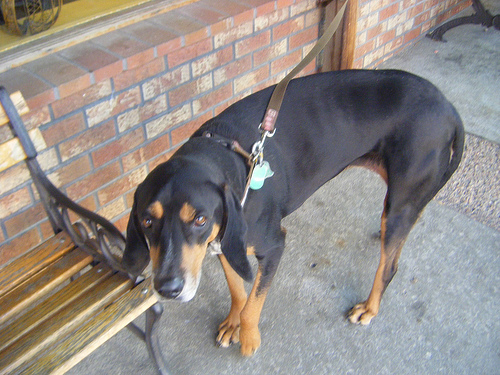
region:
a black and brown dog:
[111, 37, 476, 362]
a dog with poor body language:
[123, 60, 480, 362]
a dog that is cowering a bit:
[117, 57, 462, 364]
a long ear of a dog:
[210, 175, 264, 290]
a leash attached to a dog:
[250, 0, 353, 162]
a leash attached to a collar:
[249, 1, 351, 161]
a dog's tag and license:
[244, 134, 274, 202]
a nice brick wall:
[0, 4, 315, 221]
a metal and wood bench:
[0, 82, 176, 370]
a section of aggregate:
[433, 108, 495, 230]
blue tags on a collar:
[251, 160, 284, 191]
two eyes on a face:
[139, 214, 225, 230]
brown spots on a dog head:
[146, 193, 193, 223]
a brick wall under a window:
[116, 53, 229, 107]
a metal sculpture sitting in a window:
[1, 2, 69, 35]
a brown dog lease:
[291, 21, 339, 74]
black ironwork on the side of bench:
[40, 169, 128, 266]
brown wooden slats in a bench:
[26, 309, 99, 346]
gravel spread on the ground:
[457, 154, 497, 216]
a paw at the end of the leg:
[342, 301, 372, 328]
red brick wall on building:
[105, 33, 247, 110]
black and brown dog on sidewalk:
[125, 50, 471, 363]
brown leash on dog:
[236, 11, 349, 167]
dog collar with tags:
[219, 138, 276, 197]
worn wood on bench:
[4, 218, 94, 365]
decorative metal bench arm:
[28, 165, 142, 291]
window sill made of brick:
[16, 9, 247, 76]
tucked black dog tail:
[414, 113, 482, 209]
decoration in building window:
[7, 1, 74, 46]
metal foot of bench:
[415, 7, 487, 53]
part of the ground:
[438, 290, 480, 350]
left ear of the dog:
[218, 225, 258, 285]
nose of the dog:
[151, 270, 181, 302]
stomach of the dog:
[282, 128, 369, 173]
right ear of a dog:
[116, 228, 153, 263]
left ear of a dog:
[192, 205, 207, 228]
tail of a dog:
[445, 138, 467, 182]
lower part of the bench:
[28, 289, 94, 366]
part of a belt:
[298, 23, 337, 59]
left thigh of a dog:
[386, 181, 419, 231]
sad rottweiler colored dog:
[117, 157, 224, 329]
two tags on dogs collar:
[237, 148, 289, 191]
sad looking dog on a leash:
[117, 173, 262, 301]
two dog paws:
[201, 307, 290, 367]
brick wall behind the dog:
[50, 72, 182, 137]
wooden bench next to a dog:
[0, 117, 61, 368]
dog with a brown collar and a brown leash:
[167, 48, 343, 259]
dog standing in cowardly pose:
[127, 44, 482, 331]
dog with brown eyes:
[112, 154, 272, 311]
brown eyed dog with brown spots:
[83, 153, 282, 318]